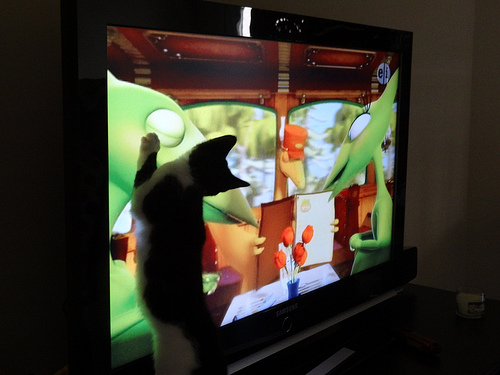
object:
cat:
[132, 132, 250, 372]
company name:
[276, 303, 298, 318]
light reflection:
[236, 4, 255, 38]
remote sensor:
[274, 16, 306, 35]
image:
[103, 24, 402, 369]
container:
[456, 286, 485, 319]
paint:
[3, 2, 500, 372]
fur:
[134, 131, 252, 374]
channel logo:
[377, 62, 391, 84]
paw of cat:
[139, 132, 161, 153]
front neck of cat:
[162, 152, 193, 190]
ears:
[206, 134, 236, 158]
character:
[321, 67, 401, 275]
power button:
[282, 316, 292, 332]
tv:
[58, 0, 420, 374]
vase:
[286, 277, 300, 300]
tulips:
[273, 248, 291, 283]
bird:
[253, 124, 339, 255]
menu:
[256, 189, 336, 288]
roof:
[107, 26, 399, 105]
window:
[179, 101, 278, 208]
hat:
[283, 124, 307, 158]